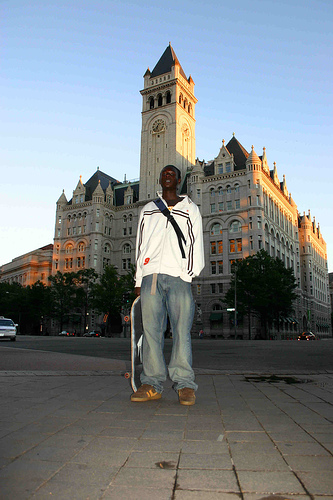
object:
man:
[124, 165, 205, 407]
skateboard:
[124, 296, 145, 393]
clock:
[148, 115, 166, 135]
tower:
[138, 41, 194, 205]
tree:
[225, 247, 301, 341]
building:
[185, 128, 333, 340]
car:
[0, 316, 19, 341]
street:
[2, 340, 114, 479]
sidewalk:
[24, 396, 302, 497]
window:
[217, 160, 231, 172]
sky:
[6, 12, 139, 140]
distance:
[134, 23, 192, 42]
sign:
[227, 308, 235, 312]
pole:
[233, 265, 238, 339]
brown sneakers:
[131, 381, 197, 405]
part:
[40, 403, 72, 429]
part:
[135, 315, 141, 329]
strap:
[153, 195, 187, 260]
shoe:
[178, 384, 196, 406]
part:
[10, 327, 14, 335]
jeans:
[140, 272, 199, 393]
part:
[237, 150, 243, 156]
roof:
[204, 135, 252, 175]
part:
[291, 347, 309, 358]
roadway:
[263, 340, 333, 382]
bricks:
[147, 423, 233, 459]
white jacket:
[134, 190, 206, 287]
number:
[143, 258, 150, 266]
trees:
[0, 262, 134, 331]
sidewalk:
[35, 330, 109, 349]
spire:
[138, 38, 192, 84]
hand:
[134, 286, 141, 297]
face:
[151, 119, 166, 135]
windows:
[206, 182, 250, 216]